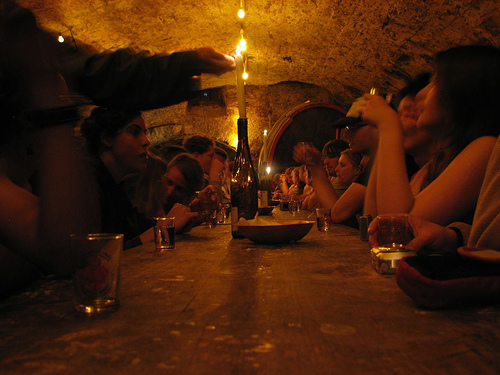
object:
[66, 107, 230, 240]
people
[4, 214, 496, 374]
table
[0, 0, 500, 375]
room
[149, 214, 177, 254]
glass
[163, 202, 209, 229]
hand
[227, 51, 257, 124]
candle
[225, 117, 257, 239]
bottle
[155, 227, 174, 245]
liquid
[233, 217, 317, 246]
bowl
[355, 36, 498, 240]
woman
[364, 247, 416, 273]
plate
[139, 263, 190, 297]
stains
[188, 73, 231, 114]
alcohol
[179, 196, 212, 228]
food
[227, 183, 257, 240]
wine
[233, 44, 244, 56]
flame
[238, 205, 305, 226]
snacks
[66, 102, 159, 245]
man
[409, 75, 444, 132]
face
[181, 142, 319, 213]
friends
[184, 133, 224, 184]
person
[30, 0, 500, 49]
ceiling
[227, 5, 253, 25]
light